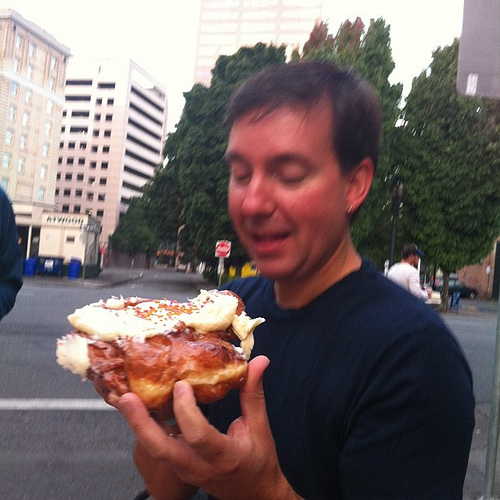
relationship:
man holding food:
[109, 60, 477, 500] [56, 288, 267, 424]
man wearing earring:
[109, 60, 477, 500] [348, 204, 356, 214]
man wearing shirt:
[109, 60, 477, 500] [134, 259, 476, 499]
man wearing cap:
[387, 242, 434, 302] [402, 243, 428, 259]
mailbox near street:
[450, 290, 462, 315] [2, 266, 500, 499]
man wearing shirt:
[387, 242, 434, 302] [385, 261, 430, 304]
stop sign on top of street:
[216, 240, 232, 260] [2, 266, 500, 499]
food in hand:
[56, 288, 267, 424] [106, 354, 292, 499]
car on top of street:
[176, 262, 188, 274] [2, 266, 500, 499]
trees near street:
[109, 17, 500, 313] [2, 266, 500, 499]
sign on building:
[45, 215, 85, 227] [39, 209, 103, 280]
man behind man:
[387, 242, 434, 302] [109, 60, 477, 500]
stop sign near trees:
[216, 240, 232, 260] [109, 17, 500, 313]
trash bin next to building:
[67, 259, 81, 279] [39, 209, 103, 280]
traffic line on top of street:
[1, 395, 122, 411] [2, 266, 500, 499]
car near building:
[427, 277, 478, 300] [457, 238, 500, 298]